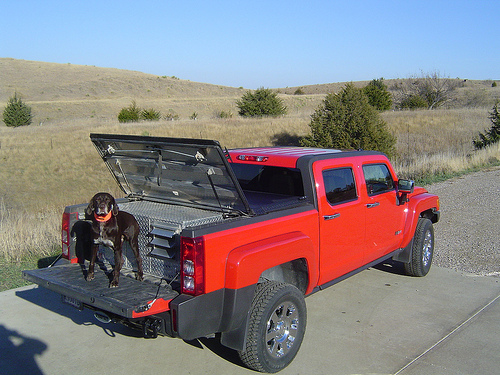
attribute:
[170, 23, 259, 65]
sky — blue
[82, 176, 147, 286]
dog — white , black 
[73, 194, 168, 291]
dog — tailgate 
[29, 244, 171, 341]
vehicle — tailgate 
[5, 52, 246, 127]
hillside — straw, covered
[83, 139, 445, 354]
vehicle — red, parked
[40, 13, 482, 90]
sky — clear, blue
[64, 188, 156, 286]
dog — standing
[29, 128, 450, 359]
truck — red, pickup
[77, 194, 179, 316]
dog — large, black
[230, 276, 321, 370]
tire — rear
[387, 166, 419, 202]
mirror — sideview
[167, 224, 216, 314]
tail light — rear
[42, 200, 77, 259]
tail light — rear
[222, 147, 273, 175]
tail light — rear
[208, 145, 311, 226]
window — rear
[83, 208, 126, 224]
dog collar — red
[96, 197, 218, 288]
bin — silver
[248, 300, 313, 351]
rim — chrome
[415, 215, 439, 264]
rim — chrome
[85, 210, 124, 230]
bandanna — red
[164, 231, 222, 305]
light — red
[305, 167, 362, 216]
window — black, tinted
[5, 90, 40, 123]
bush — green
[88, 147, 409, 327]
truck — red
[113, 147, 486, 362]
truck — red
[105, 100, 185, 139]
bush — green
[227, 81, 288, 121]
bush — green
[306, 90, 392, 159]
bush — green